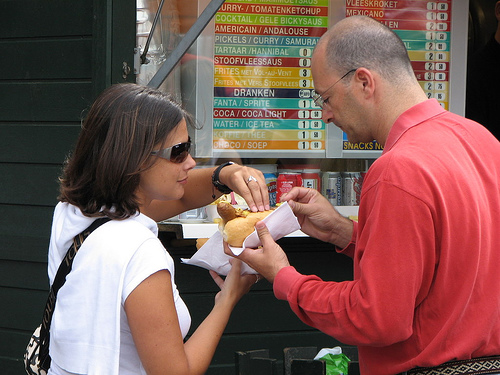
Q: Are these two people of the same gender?
A: No, they are both male and female.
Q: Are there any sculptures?
A: No, there are no sculptures.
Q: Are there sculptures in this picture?
A: No, there are no sculptures.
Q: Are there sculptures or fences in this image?
A: No, there are no sculptures or fences.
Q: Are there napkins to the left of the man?
A: Yes, there is a napkin to the left of the man.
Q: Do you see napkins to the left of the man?
A: Yes, there is a napkin to the left of the man.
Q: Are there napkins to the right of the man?
A: No, the napkin is to the left of the man.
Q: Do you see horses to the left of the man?
A: No, there is a napkin to the left of the man.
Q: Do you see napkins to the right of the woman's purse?
A: Yes, there is a napkin to the right of the purse.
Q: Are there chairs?
A: No, there are no chairs.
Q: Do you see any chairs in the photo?
A: No, there are no chairs.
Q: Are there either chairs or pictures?
A: No, there are no chairs or pictures.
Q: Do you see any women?
A: Yes, there is a woman.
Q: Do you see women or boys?
A: Yes, there is a woman.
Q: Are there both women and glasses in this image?
A: Yes, there are both a woman and glasses.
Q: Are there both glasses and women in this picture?
A: Yes, there are both a woman and glasses.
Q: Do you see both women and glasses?
A: Yes, there are both a woman and glasses.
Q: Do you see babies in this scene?
A: No, there are no babies.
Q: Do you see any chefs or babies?
A: No, there are no babies or chefs.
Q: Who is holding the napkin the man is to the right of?
A: The woman is holding the napkin.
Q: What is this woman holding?
A: The woman is holding the napkin.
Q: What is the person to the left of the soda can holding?
A: The woman is holding the napkin.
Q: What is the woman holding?
A: The woman is holding the napkin.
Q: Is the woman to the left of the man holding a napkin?
A: Yes, the woman is holding a napkin.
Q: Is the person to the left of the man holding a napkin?
A: Yes, the woman is holding a napkin.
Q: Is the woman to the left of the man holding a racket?
A: No, the woman is holding a napkin.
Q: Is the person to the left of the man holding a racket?
A: No, the woman is holding a napkin.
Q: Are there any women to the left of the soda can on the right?
A: Yes, there is a woman to the left of the soda can.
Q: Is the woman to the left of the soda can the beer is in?
A: Yes, the woman is to the left of the soda can.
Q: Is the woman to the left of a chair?
A: No, the woman is to the left of the soda can.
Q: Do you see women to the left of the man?
A: Yes, there is a woman to the left of the man.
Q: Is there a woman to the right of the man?
A: No, the woman is to the left of the man.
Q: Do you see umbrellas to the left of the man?
A: No, there is a woman to the left of the man.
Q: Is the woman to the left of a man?
A: Yes, the woman is to the left of a man.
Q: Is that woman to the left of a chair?
A: No, the woman is to the left of a man.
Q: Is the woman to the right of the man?
A: No, the woman is to the left of the man.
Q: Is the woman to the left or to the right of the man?
A: The woman is to the left of the man.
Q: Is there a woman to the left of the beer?
A: Yes, there is a woman to the left of the beer.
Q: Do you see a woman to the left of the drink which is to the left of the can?
A: Yes, there is a woman to the left of the beer.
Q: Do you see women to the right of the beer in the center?
A: No, the woman is to the left of the beer.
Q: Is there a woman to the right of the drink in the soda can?
A: No, the woman is to the left of the beer.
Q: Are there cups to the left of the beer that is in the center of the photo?
A: No, there is a woman to the left of the beer.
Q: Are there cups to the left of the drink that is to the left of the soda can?
A: No, there is a woman to the left of the beer.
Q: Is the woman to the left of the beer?
A: Yes, the woman is to the left of the beer.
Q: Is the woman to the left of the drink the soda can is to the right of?
A: Yes, the woman is to the left of the beer.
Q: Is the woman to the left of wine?
A: No, the woman is to the left of the beer.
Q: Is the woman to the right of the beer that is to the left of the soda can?
A: No, the woman is to the left of the beer.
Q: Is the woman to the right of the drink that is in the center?
A: No, the woman is to the left of the beer.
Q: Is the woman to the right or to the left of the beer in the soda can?
A: The woman is to the left of the beer.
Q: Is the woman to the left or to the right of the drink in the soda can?
A: The woman is to the left of the beer.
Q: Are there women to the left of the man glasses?
A: Yes, there is a woman to the left of the glasses.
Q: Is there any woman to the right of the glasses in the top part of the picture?
A: No, the woman is to the left of the glasses.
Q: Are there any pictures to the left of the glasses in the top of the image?
A: No, there is a woman to the left of the glasses.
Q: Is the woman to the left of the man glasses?
A: Yes, the woman is to the left of the glasses.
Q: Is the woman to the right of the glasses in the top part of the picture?
A: No, the woman is to the left of the glasses.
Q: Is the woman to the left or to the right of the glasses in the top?
A: The woman is to the left of the glasses.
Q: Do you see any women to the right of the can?
A: No, the woman is to the left of the can.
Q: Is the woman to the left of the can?
A: Yes, the woman is to the left of the can.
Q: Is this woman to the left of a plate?
A: No, the woman is to the left of the can.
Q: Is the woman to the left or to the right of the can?
A: The woman is to the left of the can.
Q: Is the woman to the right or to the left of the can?
A: The woman is to the left of the can.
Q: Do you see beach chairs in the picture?
A: No, there are no beach chairs.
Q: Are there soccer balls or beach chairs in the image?
A: No, there are no beach chairs or soccer balls.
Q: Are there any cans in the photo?
A: Yes, there is a can.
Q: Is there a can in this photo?
A: Yes, there is a can.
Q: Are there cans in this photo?
A: Yes, there is a can.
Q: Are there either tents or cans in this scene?
A: Yes, there is a can.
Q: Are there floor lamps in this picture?
A: No, there are no floor lamps.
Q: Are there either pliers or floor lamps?
A: No, there are no floor lamps or pliers.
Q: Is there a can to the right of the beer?
A: Yes, there is a can to the right of the beer.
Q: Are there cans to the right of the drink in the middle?
A: Yes, there is a can to the right of the beer.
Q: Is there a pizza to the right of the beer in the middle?
A: No, there is a can to the right of the beer.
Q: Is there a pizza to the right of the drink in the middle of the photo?
A: No, there is a can to the right of the beer.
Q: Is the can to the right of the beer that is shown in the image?
A: Yes, the can is to the right of the beer.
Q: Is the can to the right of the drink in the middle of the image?
A: Yes, the can is to the right of the beer.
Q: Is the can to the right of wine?
A: No, the can is to the right of the beer.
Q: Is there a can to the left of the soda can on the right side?
A: Yes, there is a can to the left of the soda can.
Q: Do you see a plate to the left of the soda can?
A: No, there is a can to the left of the soda can.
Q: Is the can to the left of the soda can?
A: Yes, the can is to the left of the soda can.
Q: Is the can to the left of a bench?
A: No, the can is to the left of the soda can.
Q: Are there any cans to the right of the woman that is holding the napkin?
A: Yes, there is a can to the right of the woman.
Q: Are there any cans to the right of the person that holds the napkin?
A: Yes, there is a can to the right of the woman.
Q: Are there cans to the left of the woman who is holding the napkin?
A: No, the can is to the right of the woman.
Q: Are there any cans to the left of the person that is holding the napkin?
A: No, the can is to the right of the woman.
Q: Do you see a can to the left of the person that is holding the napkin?
A: No, the can is to the right of the woman.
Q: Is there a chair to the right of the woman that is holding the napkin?
A: No, there is a can to the right of the woman.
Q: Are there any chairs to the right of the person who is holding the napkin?
A: No, there is a can to the right of the woman.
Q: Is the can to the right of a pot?
A: No, the can is to the right of the woman.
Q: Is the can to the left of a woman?
A: No, the can is to the right of a woman.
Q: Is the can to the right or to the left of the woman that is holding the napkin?
A: The can is to the right of the woman.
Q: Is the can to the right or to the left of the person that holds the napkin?
A: The can is to the right of the woman.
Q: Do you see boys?
A: No, there are no boys.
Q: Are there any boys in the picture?
A: No, there are no boys.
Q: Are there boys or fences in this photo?
A: No, there are no boys or fences.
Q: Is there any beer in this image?
A: Yes, there is beer.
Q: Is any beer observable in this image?
A: Yes, there is beer.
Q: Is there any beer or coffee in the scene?
A: Yes, there is beer.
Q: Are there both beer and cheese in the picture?
A: No, there is beer but no cheese.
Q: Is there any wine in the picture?
A: No, there is no wine.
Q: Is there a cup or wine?
A: No, there are no wine or cups.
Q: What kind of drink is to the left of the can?
A: The drink is beer.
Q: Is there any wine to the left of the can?
A: No, there is beer to the left of the can.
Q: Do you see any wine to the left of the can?
A: No, there is beer to the left of the can.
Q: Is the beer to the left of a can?
A: Yes, the beer is to the left of a can.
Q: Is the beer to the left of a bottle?
A: No, the beer is to the left of a can.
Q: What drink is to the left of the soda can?
A: The drink is beer.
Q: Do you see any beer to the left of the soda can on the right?
A: Yes, there is beer to the left of the soda can.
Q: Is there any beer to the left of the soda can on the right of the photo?
A: Yes, there is beer to the left of the soda can.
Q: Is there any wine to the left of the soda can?
A: No, there is beer to the left of the soda can.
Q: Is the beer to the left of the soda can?
A: Yes, the beer is to the left of the soda can.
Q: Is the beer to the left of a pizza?
A: No, the beer is to the left of the soda can.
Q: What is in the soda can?
A: The beer is in the soda can.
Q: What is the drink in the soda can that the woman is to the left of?
A: The drink is beer.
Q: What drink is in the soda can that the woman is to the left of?
A: The drink is beer.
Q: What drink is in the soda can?
A: The drink is beer.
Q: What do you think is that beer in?
A: The beer is in the soda can.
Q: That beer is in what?
A: The beer is in the soda can.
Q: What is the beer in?
A: The beer is in the soda can.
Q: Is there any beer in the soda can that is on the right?
A: Yes, there is beer in the soda can.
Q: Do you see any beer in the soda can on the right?
A: Yes, there is beer in the soda can.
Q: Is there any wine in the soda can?
A: No, there is beer in the soda can.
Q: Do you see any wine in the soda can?
A: No, there is beer in the soda can.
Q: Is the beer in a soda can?
A: Yes, the beer is in a soda can.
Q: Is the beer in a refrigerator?
A: No, the beer is in a soda can.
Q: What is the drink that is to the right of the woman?
A: The drink is beer.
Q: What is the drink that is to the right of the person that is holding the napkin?
A: The drink is beer.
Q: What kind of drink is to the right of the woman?
A: The drink is beer.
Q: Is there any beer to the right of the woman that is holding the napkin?
A: Yes, there is beer to the right of the woman.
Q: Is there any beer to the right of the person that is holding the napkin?
A: Yes, there is beer to the right of the woman.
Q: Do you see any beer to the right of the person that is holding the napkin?
A: Yes, there is beer to the right of the woman.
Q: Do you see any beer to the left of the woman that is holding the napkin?
A: No, the beer is to the right of the woman.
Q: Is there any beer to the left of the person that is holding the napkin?
A: No, the beer is to the right of the woman.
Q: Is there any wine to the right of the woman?
A: No, there is beer to the right of the woman.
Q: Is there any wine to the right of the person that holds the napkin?
A: No, there is beer to the right of the woman.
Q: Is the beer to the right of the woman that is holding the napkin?
A: Yes, the beer is to the right of the woman.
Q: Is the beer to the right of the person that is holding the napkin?
A: Yes, the beer is to the right of the woman.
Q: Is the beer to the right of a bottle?
A: No, the beer is to the right of the woman.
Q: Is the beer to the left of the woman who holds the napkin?
A: No, the beer is to the right of the woman.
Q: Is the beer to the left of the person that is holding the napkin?
A: No, the beer is to the right of the woman.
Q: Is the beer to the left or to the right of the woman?
A: The beer is to the right of the woman.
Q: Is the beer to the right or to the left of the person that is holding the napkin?
A: The beer is to the right of the woman.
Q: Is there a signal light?
A: No, there are no traffic lights.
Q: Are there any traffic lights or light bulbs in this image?
A: No, there are no traffic lights or light bulbs.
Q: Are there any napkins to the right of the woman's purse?
A: Yes, there is a napkin to the right of the purse.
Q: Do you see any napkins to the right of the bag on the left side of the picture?
A: Yes, there is a napkin to the right of the purse.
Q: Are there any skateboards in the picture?
A: No, there are no skateboards.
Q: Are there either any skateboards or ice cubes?
A: No, there are no skateboards or ice cubes.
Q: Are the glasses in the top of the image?
A: Yes, the glasses are in the top of the image.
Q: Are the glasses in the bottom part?
A: No, the glasses are in the top of the image.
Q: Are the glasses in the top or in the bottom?
A: The glasses are in the top of the image.